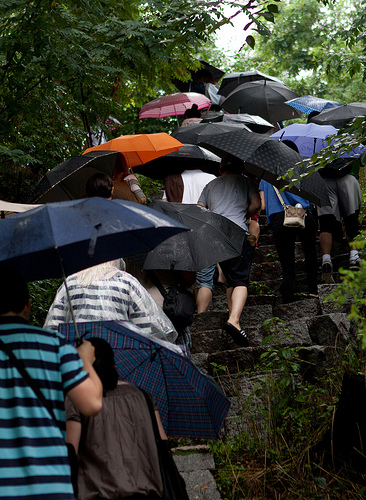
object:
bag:
[163, 287, 195, 329]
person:
[143, 269, 196, 360]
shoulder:
[147, 284, 162, 298]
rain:
[212, 18, 287, 51]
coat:
[43, 257, 179, 342]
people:
[112, 153, 147, 204]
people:
[65, 337, 170, 500]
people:
[259, 139, 318, 299]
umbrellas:
[138, 91, 212, 129]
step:
[189, 340, 309, 375]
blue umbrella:
[270, 121, 365, 159]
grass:
[210, 317, 363, 497]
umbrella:
[284, 95, 343, 114]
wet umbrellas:
[31, 61, 365, 201]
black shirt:
[0, 316, 89, 500]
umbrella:
[0, 197, 193, 345]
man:
[197, 157, 261, 346]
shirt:
[198, 173, 260, 232]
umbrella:
[220, 77, 302, 124]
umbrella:
[196, 131, 333, 209]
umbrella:
[140, 200, 250, 272]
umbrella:
[27, 149, 120, 205]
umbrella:
[310, 102, 366, 125]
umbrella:
[58, 320, 232, 442]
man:
[0, 274, 104, 500]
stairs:
[165, 214, 356, 488]